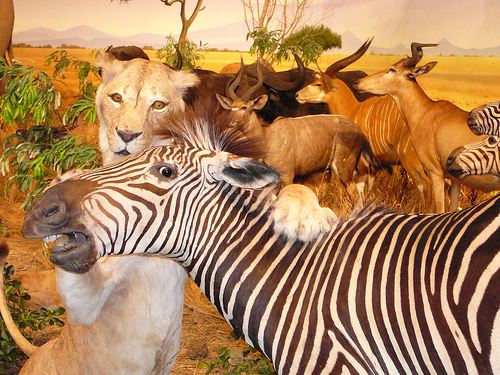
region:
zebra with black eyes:
[158, 160, 179, 184]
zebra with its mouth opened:
[1, 203, 101, 287]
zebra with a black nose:
[4, 193, 98, 274]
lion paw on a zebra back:
[261, 180, 334, 259]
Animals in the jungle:
[21, 12, 475, 370]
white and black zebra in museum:
[22, 120, 499, 372]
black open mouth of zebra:
[24, 175, 100, 273]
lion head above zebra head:
[86, 47, 201, 167]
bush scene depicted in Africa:
[4, 6, 490, 370]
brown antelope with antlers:
[362, 35, 493, 212]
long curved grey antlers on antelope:
[226, 50, 268, 111]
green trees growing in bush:
[246, 12, 345, 77]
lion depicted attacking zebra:
[16, 54, 499, 367]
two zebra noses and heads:
[434, 97, 499, 202]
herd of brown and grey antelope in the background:
[81, 28, 471, 219]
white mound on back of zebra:
[263, 180, 362, 246]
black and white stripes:
[314, 274, 412, 330]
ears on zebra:
[208, 153, 278, 198]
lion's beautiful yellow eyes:
[87, 82, 182, 117]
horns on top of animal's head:
[316, 40, 386, 82]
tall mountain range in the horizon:
[32, 12, 105, 44]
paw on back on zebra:
[268, 182, 327, 242]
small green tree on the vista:
[257, 18, 347, 63]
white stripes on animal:
[346, 99, 416, 141]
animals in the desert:
[42, 30, 487, 335]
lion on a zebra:
[14, 48, 356, 309]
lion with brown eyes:
[146, 94, 171, 116]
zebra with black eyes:
[156, 168, 181, 181]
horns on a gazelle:
[398, 28, 433, 78]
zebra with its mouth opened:
[28, 206, 100, 280]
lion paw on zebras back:
[248, 176, 333, 246]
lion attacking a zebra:
[17, 50, 342, 327]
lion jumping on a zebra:
[21, 38, 354, 363]